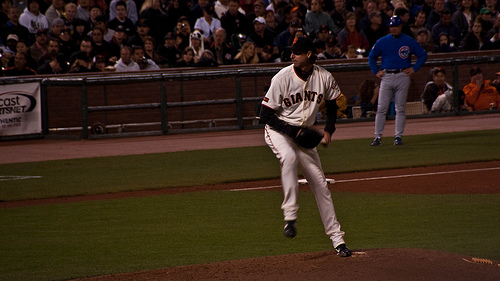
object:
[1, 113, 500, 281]
ground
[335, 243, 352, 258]
shoe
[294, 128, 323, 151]
glove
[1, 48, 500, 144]
fence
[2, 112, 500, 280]
field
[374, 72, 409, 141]
trouser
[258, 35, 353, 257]
player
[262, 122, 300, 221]
leg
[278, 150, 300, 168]
knee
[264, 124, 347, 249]
trouser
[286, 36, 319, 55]
cap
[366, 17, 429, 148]
people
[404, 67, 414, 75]
hand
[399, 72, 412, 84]
pocket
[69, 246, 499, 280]
mound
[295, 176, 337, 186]
base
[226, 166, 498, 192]
line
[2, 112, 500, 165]
path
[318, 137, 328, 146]
baseball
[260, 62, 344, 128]
shirt